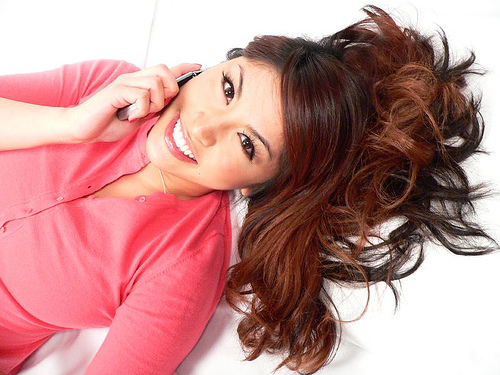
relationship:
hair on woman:
[223, 4, 499, 375] [37, 44, 412, 360]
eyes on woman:
[205, 63, 300, 199] [15, 51, 406, 365]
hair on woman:
[265, 43, 469, 371] [29, 25, 388, 337]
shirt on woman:
[0, 58, 233, 375] [59, 35, 407, 346]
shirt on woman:
[20, 212, 117, 269] [67, 56, 363, 264]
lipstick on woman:
[162, 116, 193, 169] [94, 49, 321, 233]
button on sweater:
[137, 194, 149, 204] [70, 237, 157, 284]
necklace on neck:
[140, 161, 176, 197] [140, 163, 184, 193]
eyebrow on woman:
[224, 68, 272, 98] [39, 129, 254, 218]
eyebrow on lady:
[230, 107, 281, 160] [0, 5, 500, 375]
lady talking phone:
[0, 5, 500, 375] [108, 66, 198, 124]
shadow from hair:
[283, 325, 382, 367] [279, 21, 472, 210]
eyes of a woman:
[235, 130, 260, 164] [1, 30, 438, 341]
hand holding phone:
[66, 60, 203, 150] [113, 72, 195, 120]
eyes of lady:
[218, 69, 260, 166] [0, 5, 500, 375]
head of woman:
[152, 36, 332, 194] [6, 22, 452, 368]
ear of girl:
[240, 181, 268, 197] [6, 34, 366, 364]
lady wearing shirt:
[7, 38, 354, 368] [0, 57, 236, 372]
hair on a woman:
[223, 4, 499, 375] [123, 35, 341, 269]